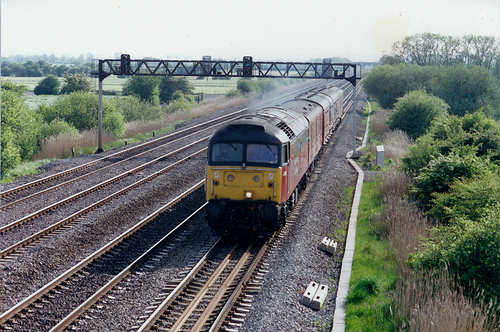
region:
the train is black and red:
[205, 85, 350, 210]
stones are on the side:
[298, 277, 329, 317]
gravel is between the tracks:
[73, 217, 158, 278]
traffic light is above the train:
[115, 49, 264, 86]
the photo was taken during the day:
[5, 12, 487, 330]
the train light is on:
[240, 188, 257, 200]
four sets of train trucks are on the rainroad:
[0, 177, 248, 305]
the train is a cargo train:
[208, 87, 353, 224]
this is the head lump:
[235, 181, 260, 206]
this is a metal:
[240, 268, 251, 292]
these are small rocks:
[281, 257, 294, 294]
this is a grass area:
[357, 235, 386, 297]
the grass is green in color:
[355, 234, 375, 269]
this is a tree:
[384, 84, 428, 119]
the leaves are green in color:
[403, 96, 441, 128]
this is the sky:
[57, 2, 136, 34]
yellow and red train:
[205, 88, 345, 213]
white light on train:
[225, 182, 257, 209]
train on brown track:
[167, 206, 269, 329]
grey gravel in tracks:
[26, 182, 264, 331]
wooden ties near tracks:
[299, 228, 343, 320]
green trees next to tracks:
[392, 58, 499, 310]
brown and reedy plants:
[376, 114, 482, 328]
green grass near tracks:
[340, 150, 429, 331]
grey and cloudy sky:
[112, 8, 343, 59]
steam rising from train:
[233, 73, 303, 124]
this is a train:
[197, 79, 352, 234]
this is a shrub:
[6, 88, 55, 161]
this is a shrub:
[375, 77, 446, 144]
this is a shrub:
[57, 73, 131, 146]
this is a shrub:
[124, 58, 164, 118]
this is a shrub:
[27, 61, 72, 101]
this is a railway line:
[84, 234, 127, 309]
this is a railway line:
[136, 204, 183, 266]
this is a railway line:
[20, 265, 98, 325]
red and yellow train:
[213, 78, 352, 235]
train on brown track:
[168, 69, 335, 331]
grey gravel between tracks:
[4, 195, 286, 330]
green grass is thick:
[349, 183, 386, 325]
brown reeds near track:
[350, 201, 465, 331]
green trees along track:
[382, 67, 480, 279]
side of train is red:
[283, 101, 346, 188]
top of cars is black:
[218, 80, 330, 133]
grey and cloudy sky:
[147, 14, 353, 51]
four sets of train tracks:
[2, 153, 272, 325]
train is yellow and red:
[209, 87, 343, 214]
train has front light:
[240, 187, 260, 202]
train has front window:
[241, 140, 281, 167]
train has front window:
[207, 138, 244, 168]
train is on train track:
[149, 80, 356, 326]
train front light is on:
[238, 184, 263, 204]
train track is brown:
[4, 177, 225, 329]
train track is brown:
[130, 223, 260, 328]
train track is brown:
[3, 139, 221, 270]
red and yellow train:
[201, 73, 368, 238]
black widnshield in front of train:
[208, 140, 278, 165]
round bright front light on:
[241, 189, 255, 200]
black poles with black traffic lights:
[92, 55, 354, 154]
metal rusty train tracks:
[0, 63, 349, 330]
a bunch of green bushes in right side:
[362, 58, 498, 298]